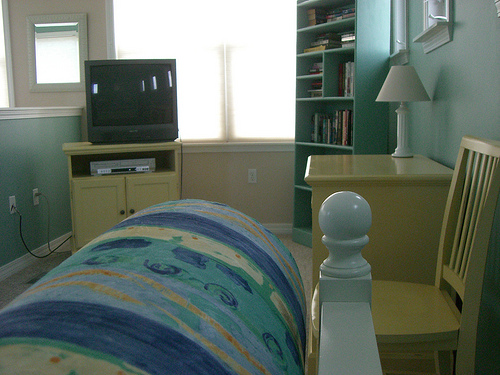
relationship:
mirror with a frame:
[36, 21, 79, 83] [29, 13, 88, 92]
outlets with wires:
[9, 189, 41, 214] [12, 203, 73, 258]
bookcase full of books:
[294, 0, 391, 248] [300, 4, 354, 147]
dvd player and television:
[88, 159, 156, 174] [84, 58, 177, 143]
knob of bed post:
[320, 192, 371, 255] [315, 191, 381, 374]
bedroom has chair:
[0, 0, 499, 374] [312, 138, 499, 370]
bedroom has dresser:
[0, 0, 499, 374] [306, 152, 461, 283]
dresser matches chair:
[306, 152, 461, 283] [312, 138, 499, 370]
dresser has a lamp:
[306, 152, 461, 283] [373, 63, 432, 159]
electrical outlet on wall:
[248, 168, 260, 185] [188, 150, 292, 217]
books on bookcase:
[300, 4, 354, 147] [294, 0, 391, 248]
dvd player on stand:
[88, 159, 156, 174] [64, 139, 182, 246]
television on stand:
[84, 58, 177, 143] [64, 139, 182, 246]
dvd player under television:
[88, 159, 156, 174] [84, 58, 177, 143]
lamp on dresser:
[373, 63, 432, 159] [306, 152, 461, 283]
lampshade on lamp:
[376, 65, 430, 101] [373, 63, 432, 159]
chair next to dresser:
[312, 138, 499, 370] [306, 152, 461, 283]